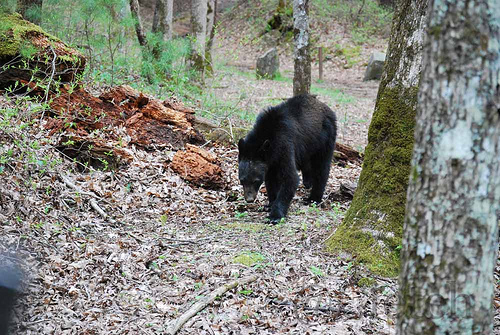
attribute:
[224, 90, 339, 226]
bear — adult, black, wild, walking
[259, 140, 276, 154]
ear — black, furry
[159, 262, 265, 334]
stick — brown, long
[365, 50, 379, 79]
rock — grey, large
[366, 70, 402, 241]
moss — growing, green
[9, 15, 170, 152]
tree — rotten, dead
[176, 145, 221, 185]
wood — rotten